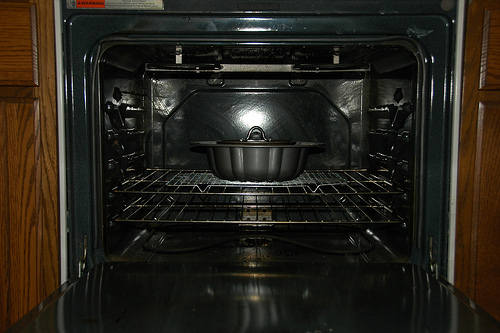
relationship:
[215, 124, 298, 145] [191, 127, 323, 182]
lid covering baking pan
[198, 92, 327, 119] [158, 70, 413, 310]
wall supporting oven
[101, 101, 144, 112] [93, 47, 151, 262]
ridge built into wall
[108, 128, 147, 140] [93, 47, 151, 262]
ridge built into wall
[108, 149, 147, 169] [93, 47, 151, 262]
ridge built into wall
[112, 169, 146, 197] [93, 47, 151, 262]
ridge built into wall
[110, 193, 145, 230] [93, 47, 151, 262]
ridge built into wall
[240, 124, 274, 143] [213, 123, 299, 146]
handle attached to lid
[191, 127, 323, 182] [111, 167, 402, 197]
baking pan sitting on top of oven rack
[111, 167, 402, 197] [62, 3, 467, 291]
oven rack belonging to oven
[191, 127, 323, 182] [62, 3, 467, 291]
baking pan sitting inside oven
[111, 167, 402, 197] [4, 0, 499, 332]
oven rack sitting inside oven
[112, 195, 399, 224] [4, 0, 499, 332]
oven rack sitting inside oven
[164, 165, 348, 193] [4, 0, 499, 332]
rack sitting inside oven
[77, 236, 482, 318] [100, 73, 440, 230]
door leading to oven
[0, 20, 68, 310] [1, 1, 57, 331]
door leading to cabinet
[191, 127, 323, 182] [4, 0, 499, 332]
baking pan sitting inside oven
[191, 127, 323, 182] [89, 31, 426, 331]
baking pan sitting inside oven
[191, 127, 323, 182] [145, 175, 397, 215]
baking pan sitting on top of rack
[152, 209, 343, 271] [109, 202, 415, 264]
burner built into bottom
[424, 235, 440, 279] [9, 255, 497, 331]
hook attaching door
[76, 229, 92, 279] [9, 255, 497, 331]
hook attaching door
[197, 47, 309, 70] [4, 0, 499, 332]
hook mounted on oven